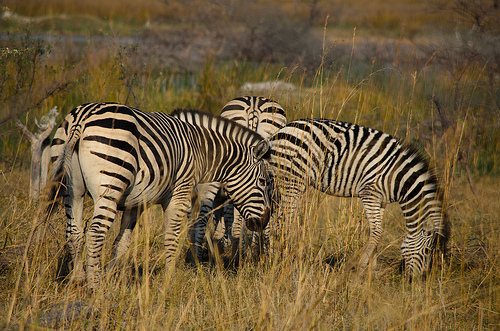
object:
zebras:
[237, 118, 451, 290]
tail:
[39, 124, 83, 225]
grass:
[99, 275, 497, 330]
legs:
[84, 194, 118, 290]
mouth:
[247, 218, 267, 233]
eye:
[259, 178, 266, 183]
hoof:
[72, 277, 87, 287]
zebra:
[33, 101, 273, 293]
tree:
[402, 2, 500, 151]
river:
[4, 30, 138, 49]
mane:
[170, 106, 268, 158]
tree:
[236, 0, 292, 57]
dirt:
[316, 25, 399, 46]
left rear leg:
[63, 181, 87, 288]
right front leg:
[161, 184, 194, 280]